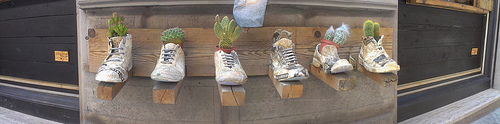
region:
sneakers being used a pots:
[72, 14, 405, 106]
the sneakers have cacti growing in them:
[92, 18, 414, 65]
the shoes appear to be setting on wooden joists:
[88, 15, 399, 108]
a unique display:
[84, 18, 404, 105]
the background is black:
[8, 5, 64, 104]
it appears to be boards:
[29, 28, 45, 73]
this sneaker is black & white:
[263, 33, 310, 80]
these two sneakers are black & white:
[308, 35, 412, 82]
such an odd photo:
[94, 10, 396, 101]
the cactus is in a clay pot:
[313, 33, 337, 52]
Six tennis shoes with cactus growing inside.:
[95, 10, 400, 86]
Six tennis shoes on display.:
[94, 32, 398, 84]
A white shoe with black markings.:
[94, 11, 132, 83]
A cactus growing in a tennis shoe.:
[104, 8, 129, 37]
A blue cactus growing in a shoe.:
[322, 23, 349, 43]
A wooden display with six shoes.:
[85, 23, 395, 108]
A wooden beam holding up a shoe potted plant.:
[216, 83, 247, 109]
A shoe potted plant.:
[212, 12, 242, 83]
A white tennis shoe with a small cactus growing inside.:
[150, 26, 183, 82]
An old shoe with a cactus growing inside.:
[357, 19, 398, 72]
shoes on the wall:
[47, 1, 472, 115]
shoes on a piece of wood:
[79, 3, 416, 118]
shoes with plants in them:
[87, 1, 449, 107]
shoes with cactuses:
[80, 8, 408, 122]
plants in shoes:
[50, 4, 301, 122]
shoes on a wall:
[101, 13, 442, 102]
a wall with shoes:
[74, 7, 452, 122]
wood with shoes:
[80, 8, 374, 119]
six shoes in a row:
[85, 14, 390, 121]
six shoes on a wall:
[77, 5, 359, 117]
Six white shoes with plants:
[94, 12, 400, 83]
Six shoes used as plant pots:
[95, 10, 400, 83]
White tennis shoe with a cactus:
[210, 10, 245, 84]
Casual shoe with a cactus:
[311, 23, 353, 76]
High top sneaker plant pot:
[95, 11, 133, 85]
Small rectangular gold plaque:
[468, 43, 480, 58]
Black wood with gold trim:
[0, 0, 79, 92]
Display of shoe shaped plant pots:
[75, 1, 397, 122]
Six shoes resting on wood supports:
[94, 31, 399, 107]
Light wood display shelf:
[86, 23, 397, 105]